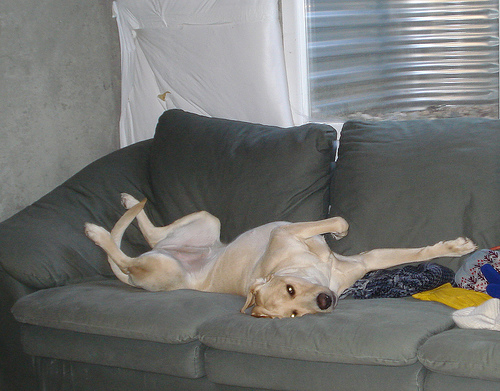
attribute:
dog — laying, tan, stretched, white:
[84, 191, 479, 318]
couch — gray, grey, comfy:
[1, 108, 496, 390]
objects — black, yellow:
[343, 260, 489, 314]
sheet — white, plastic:
[112, 4, 310, 149]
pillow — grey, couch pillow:
[322, 117, 498, 271]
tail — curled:
[104, 196, 146, 283]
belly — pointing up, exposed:
[176, 224, 253, 279]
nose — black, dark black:
[317, 292, 333, 311]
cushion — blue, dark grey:
[12, 278, 246, 389]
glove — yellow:
[413, 283, 490, 311]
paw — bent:
[328, 220, 350, 240]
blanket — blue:
[334, 261, 452, 300]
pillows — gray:
[150, 108, 499, 255]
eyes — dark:
[285, 284, 299, 317]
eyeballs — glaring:
[287, 285, 301, 317]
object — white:
[453, 298, 498, 332]